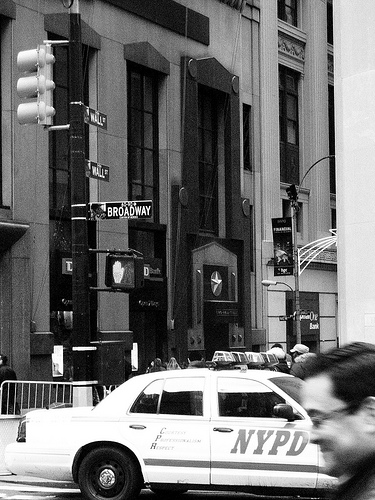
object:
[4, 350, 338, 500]
police car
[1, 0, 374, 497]
new york city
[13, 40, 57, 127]
traffic light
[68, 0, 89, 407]
pole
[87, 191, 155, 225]
street sign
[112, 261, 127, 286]
hand signal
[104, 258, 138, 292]
light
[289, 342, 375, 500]
man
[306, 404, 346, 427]
glasses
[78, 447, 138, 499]
tire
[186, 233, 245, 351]
building door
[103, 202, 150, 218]
broadway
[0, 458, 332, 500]
street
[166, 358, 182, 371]
people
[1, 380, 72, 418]
fence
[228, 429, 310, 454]
nypd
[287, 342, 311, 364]
man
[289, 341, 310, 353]
cap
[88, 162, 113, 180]
street sign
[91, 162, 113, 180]
wall st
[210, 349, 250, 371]
emergency lights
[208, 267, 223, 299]
star logo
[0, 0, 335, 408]
building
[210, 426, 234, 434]
door opener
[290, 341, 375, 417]
hair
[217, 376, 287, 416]
glass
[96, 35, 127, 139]
cement bricks